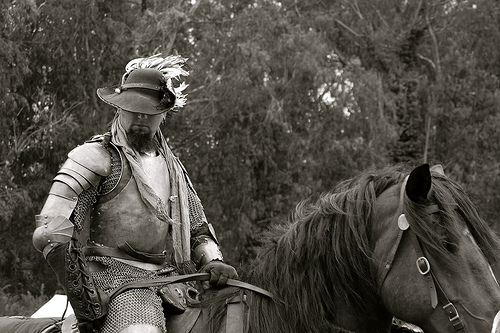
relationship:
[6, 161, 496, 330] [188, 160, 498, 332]
horse with mane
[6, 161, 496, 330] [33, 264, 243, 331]
horse wears saddle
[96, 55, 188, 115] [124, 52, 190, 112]
hat has feathers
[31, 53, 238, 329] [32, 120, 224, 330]
man wears costume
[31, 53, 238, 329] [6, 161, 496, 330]
man sits on horse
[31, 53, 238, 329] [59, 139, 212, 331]
man wears chain maille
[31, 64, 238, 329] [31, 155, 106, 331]
man has arm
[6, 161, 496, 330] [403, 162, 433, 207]
horse has ear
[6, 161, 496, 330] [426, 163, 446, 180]
horse has ear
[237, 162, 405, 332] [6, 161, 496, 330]
mane on horse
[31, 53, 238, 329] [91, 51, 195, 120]
man wearing hat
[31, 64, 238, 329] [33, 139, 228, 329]
man wearing armor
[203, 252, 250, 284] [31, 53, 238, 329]
hand on man